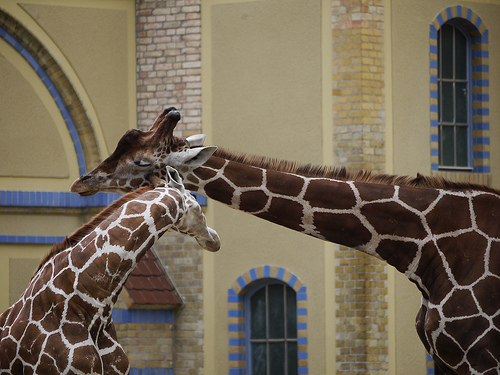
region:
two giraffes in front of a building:
[2, 104, 492, 371]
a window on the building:
[223, 259, 313, 374]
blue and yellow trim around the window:
[223, 263, 310, 373]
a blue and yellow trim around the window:
[422, 4, 494, 186]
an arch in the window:
[1, 0, 128, 207]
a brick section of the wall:
[130, 1, 206, 373]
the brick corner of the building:
[325, 0, 395, 373]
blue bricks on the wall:
[104, 307, 177, 329]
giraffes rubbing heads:
[51, 104, 250, 268]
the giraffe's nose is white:
[165, 190, 227, 255]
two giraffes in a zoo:
[18, 20, 482, 357]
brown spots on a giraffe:
[432, 204, 480, 279]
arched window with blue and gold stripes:
[414, 0, 499, 172]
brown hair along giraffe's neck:
[205, 140, 483, 194]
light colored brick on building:
[332, 10, 386, 367]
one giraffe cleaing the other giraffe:
[63, 82, 204, 274]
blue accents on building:
[6, 175, 214, 212]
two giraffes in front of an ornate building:
[30, 41, 306, 311]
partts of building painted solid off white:
[232, 26, 309, 135]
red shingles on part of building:
[122, 243, 177, 304]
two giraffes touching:
[0, 102, 497, 374]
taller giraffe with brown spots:
[67, 84, 497, 371]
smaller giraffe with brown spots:
[1, 165, 226, 373]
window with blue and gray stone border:
[220, 259, 328, 374]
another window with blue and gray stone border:
[415, 1, 498, 193]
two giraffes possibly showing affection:
[0, 101, 493, 373]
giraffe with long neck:
[90, 89, 497, 374]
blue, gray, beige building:
[0, 0, 492, 370]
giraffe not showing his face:
[2, 163, 217, 372]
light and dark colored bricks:
[132, 0, 205, 374]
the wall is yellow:
[5, 3, 497, 368]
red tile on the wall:
[124, 251, 186, 306]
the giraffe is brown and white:
[71, 107, 498, 373]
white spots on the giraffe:
[0, 183, 222, 370]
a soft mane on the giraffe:
[187, 134, 493, 201]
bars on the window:
[245, 286, 299, 373]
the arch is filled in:
[0, 39, 88, 194]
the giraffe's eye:
[131, 158, 153, 169]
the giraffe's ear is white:
[170, 133, 215, 172]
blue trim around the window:
[220, 264, 313, 373]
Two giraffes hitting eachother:
[27, 119, 478, 373]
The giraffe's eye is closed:
[131, 150, 156, 170]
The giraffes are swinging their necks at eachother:
[35, 120, 497, 363]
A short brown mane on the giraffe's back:
[207, 133, 492, 210]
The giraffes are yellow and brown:
[5, 105, 495, 372]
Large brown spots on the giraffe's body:
[183, 163, 478, 298]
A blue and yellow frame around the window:
[220, 262, 315, 372]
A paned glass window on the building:
[249, 292, 293, 372]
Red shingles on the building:
[124, 248, 199, 310]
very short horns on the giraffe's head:
[148, 101, 190, 142]